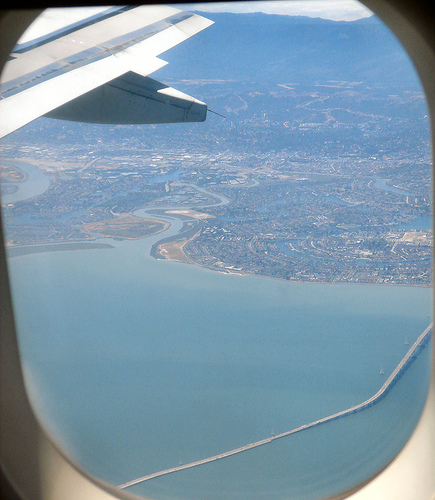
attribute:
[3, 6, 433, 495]
airplane — air 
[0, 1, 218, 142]
wing — airplane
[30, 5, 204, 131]
wing — lifted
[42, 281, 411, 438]
water — blue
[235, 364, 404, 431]
bridge — Elevated 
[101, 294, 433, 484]
bridge — long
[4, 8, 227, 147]
airplane — white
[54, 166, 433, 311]
delta — River 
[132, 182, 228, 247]
river — small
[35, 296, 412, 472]
water — blue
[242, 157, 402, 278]
homes — many 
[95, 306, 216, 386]
water — blue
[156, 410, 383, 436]
partial wing — gray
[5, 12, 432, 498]
window — round, big